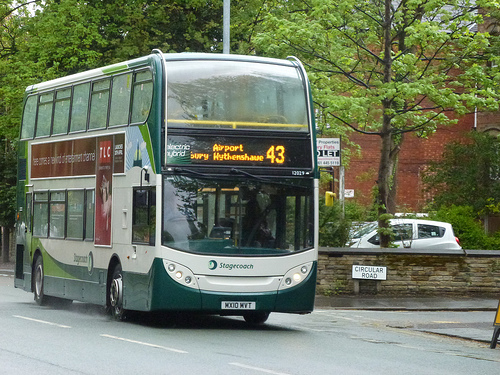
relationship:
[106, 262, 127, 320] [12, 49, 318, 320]
front tire on bus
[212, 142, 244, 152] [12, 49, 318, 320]
word on bus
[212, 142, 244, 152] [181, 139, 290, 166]
word of led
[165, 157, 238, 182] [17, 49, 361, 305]
wiper on bus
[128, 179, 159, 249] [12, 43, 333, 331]
window on bus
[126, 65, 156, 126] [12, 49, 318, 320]
window on bus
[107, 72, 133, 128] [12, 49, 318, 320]
window on bus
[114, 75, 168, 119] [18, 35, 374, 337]
window on bus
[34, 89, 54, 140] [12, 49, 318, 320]
window on bus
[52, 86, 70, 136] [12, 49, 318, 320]
window on bus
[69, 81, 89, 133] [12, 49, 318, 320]
window on bus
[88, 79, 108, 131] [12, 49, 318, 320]
window on bus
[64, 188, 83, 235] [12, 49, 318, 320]
window on bus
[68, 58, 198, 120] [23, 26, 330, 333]
top level of bus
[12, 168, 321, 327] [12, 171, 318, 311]
bottom level of bus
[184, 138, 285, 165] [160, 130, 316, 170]
digital display on bus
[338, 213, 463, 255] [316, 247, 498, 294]
car behind wall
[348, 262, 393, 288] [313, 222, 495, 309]
sign in front of wall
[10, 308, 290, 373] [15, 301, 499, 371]
traffic lines on road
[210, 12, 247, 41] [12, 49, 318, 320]
metal pole behind bus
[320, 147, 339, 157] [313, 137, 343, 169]
letters on sign